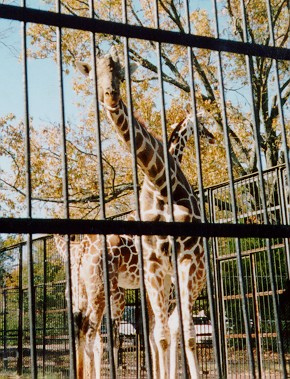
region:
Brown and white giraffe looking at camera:
[76, 44, 135, 109]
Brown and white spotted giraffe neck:
[107, 105, 188, 198]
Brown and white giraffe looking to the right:
[170, 111, 217, 148]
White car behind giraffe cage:
[187, 312, 215, 340]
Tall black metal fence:
[0, 0, 287, 378]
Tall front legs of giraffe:
[143, 263, 197, 377]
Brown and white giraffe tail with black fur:
[72, 243, 84, 327]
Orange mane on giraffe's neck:
[164, 116, 186, 145]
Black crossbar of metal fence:
[1, 211, 288, 239]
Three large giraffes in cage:
[27, 44, 221, 377]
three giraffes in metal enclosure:
[37, 33, 223, 377]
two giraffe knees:
[151, 330, 204, 354]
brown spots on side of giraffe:
[109, 238, 134, 267]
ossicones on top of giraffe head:
[90, 41, 121, 57]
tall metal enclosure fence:
[3, 0, 288, 377]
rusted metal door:
[213, 240, 289, 375]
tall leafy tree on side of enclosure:
[3, 0, 286, 258]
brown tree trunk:
[229, 164, 289, 276]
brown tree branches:
[126, 45, 209, 103]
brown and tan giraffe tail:
[68, 237, 90, 350]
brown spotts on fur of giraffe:
[139, 139, 164, 169]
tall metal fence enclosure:
[0, 0, 288, 377]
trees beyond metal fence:
[0, 0, 287, 367]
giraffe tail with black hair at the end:
[70, 234, 92, 351]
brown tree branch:
[0, 145, 248, 222]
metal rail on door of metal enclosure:
[222, 284, 288, 302]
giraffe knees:
[146, 325, 202, 351]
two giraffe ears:
[69, 56, 144, 77]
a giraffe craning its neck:
[76, 47, 183, 185]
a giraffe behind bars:
[8, 11, 288, 226]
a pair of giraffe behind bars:
[47, 43, 240, 376]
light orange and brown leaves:
[17, 0, 209, 51]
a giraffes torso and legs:
[134, 174, 213, 377]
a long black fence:
[3, 245, 281, 375]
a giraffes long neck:
[77, 47, 197, 194]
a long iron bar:
[0, 220, 287, 241]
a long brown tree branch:
[223, 0, 270, 176]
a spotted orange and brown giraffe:
[64, 7, 211, 374]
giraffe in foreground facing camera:
[73, 43, 224, 377]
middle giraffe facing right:
[74, 105, 213, 374]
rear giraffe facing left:
[44, 208, 163, 375]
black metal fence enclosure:
[1, 1, 288, 376]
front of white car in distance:
[189, 313, 216, 348]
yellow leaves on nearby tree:
[3, 0, 288, 222]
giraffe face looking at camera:
[87, 55, 130, 114]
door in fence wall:
[213, 250, 276, 377]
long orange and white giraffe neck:
[102, 96, 191, 209]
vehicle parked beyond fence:
[111, 317, 137, 342]